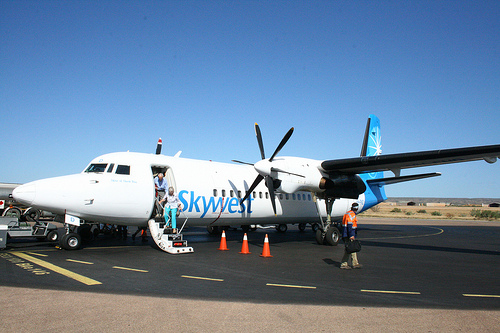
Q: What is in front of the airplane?
A: Yellow stripes.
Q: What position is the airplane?
A: It's idle.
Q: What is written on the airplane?
A: It's Skywest.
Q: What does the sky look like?
A: Clear.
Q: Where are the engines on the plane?
A: On the wing.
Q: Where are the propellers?
A: On the wing of the plane.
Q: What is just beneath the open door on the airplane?
A: Stairway.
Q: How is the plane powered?
A: Propellers.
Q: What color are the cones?
A: Orange and white.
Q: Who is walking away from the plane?
A: Man.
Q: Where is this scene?
A: Airport.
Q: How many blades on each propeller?
A: Six.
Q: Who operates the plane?
A: Skywest.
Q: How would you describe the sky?
A: Clear.